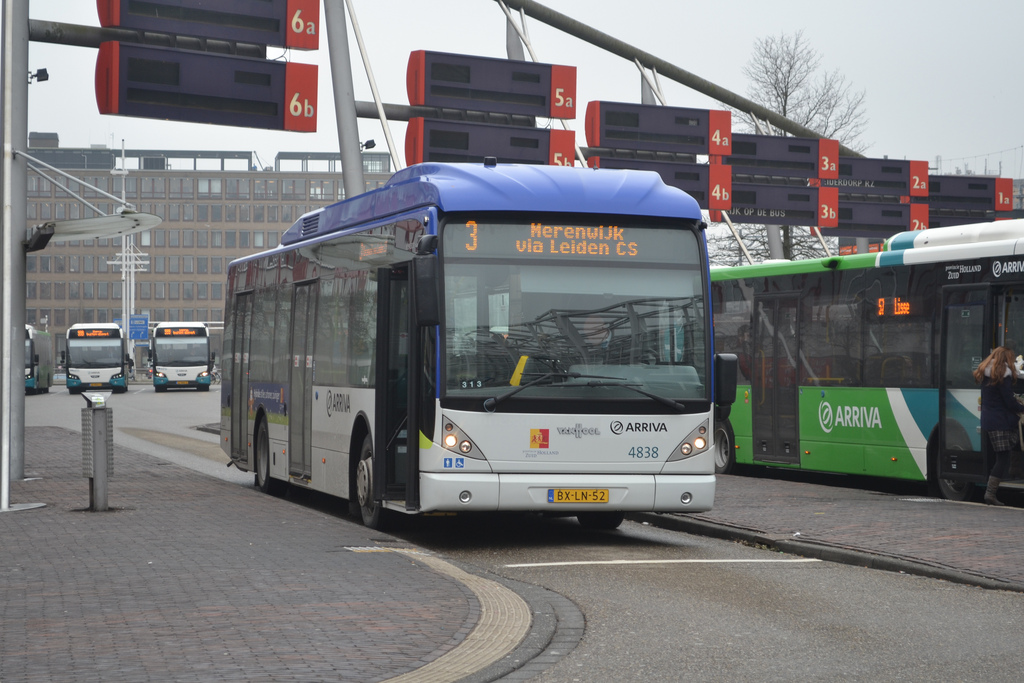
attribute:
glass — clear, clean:
[448, 219, 708, 406]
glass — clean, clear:
[863, 316, 939, 384]